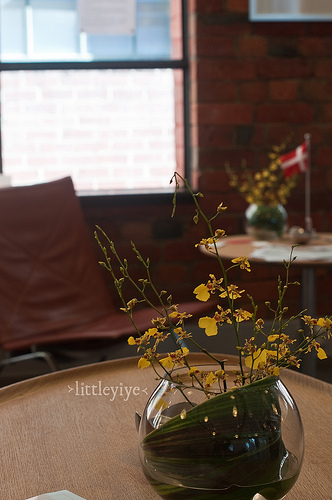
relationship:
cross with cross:
[280, 142, 310, 176] [285, 146, 312, 175]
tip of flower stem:
[163, 172, 186, 219] [173, 171, 255, 376]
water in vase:
[148, 457, 295, 496] [133, 358, 313, 495]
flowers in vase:
[126, 275, 316, 392] [133, 358, 313, 495]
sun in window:
[12, 25, 14, 27] [0, 2, 184, 189]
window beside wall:
[0, 2, 184, 189] [82, 20, 328, 321]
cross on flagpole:
[280, 142, 310, 176] [299, 134, 321, 245]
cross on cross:
[285, 146, 312, 175] [280, 142, 310, 176]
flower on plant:
[169, 322, 194, 344] [80, 170, 327, 386]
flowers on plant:
[126, 275, 316, 392] [80, 170, 327, 386]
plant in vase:
[80, 170, 327, 386] [133, 358, 313, 495]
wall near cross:
[82, 20, 328, 321] [280, 142, 310, 176]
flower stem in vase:
[173, 171, 255, 376] [133, 358, 313, 495]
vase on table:
[133, 358, 313, 495] [3, 348, 331, 500]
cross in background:
[280, 142, 310, 176] [78, 188, 328, 203]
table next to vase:
[3, 348, 331, 500] [133, 358, 313, 495]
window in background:
[0, 2, 184, 189] [78, 188, 328, 203]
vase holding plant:
[133, 358, 313, 495] [80, 170, 327, 386]